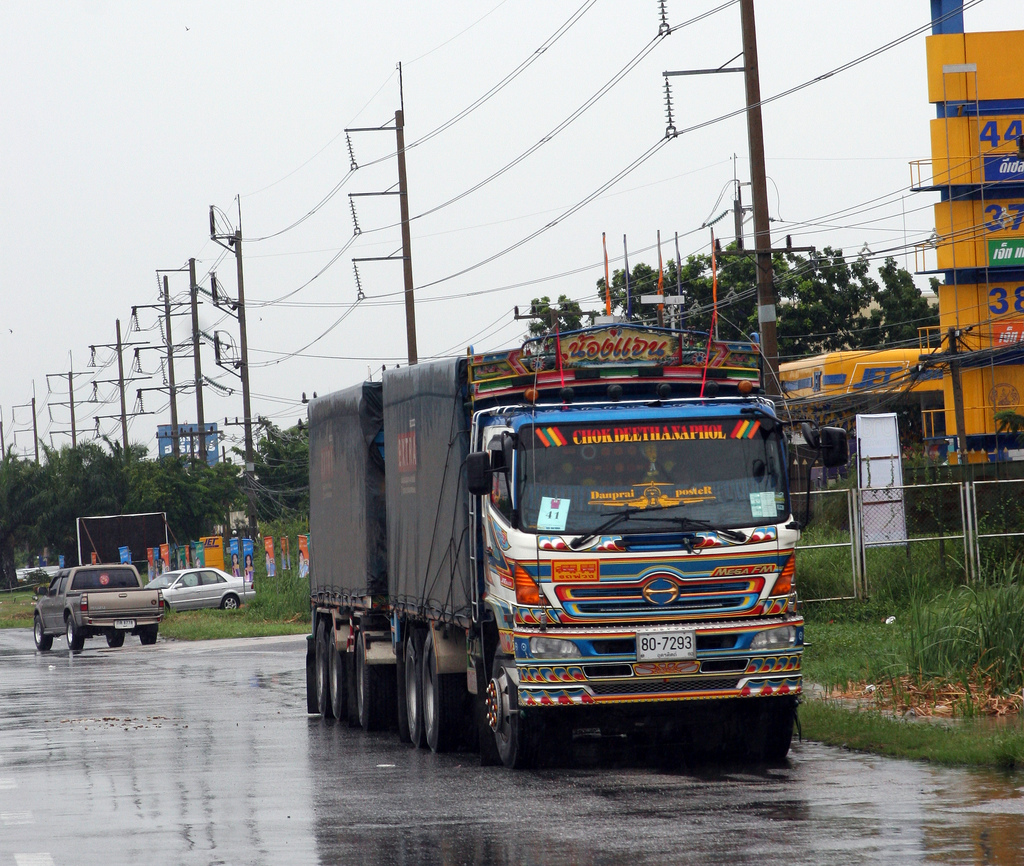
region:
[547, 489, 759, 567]
windshield wiper on the truck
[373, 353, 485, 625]
black tarp on the truck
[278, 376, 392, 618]
black tarp on the truck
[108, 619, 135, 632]
license plate on the pickup truck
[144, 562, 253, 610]
Car in front of the pickup truck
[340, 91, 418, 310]
Electric wires on the pole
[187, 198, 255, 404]
Electric wires on the pole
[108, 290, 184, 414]
Electric wires on the pole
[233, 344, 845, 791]
semi with two trailers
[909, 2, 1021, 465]
orange and blue gas price sign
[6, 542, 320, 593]
line of orange and blue flags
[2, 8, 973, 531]
powerlines on the side of the road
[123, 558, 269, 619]
silver car parked in grass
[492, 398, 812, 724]
blue and orange painting on front of truck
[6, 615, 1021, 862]
asphalt wet from the rain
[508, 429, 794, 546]
windshield on the truck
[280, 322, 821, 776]
truck in the street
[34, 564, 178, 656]
pickup truck on the street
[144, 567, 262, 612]
car parked on grass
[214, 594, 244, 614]
black tire on car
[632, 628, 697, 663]
license plate on truck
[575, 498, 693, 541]
windshield wiper on truck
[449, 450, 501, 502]
side view mirror on truck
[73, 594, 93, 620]
brake light on truck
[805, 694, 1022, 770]
green grass on the ground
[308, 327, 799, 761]
A trailer truck by the roadside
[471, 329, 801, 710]
The colorful front side of the truck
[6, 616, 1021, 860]
The cemented surface of the road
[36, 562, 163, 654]
A van on the road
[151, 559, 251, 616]
A white parked car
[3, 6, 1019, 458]
A row of electricity poles and overhead cables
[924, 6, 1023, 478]
A yellow colored building by the roadside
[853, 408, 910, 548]
An electricity junction box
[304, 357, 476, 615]
The two containers loaded on the truck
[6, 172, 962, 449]
The hazy sky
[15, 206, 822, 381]
The wooden poles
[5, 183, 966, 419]
A set of wooden poles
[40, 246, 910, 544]
A forest of trees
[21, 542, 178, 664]
The tan truck on the road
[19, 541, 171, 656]
A tan truck on the road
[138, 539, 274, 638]
The parked silver vehicle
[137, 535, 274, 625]
A parked silver vehicle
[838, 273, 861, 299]
green leaves on the tree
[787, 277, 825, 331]
green leaves on the tree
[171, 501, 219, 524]
green leaves on the tree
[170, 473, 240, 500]
green leaves on the tree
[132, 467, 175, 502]
green leaves on the tree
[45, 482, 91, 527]
green leaves on the tree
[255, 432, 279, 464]
green leaves on the tree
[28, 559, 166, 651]
tan truck with four tires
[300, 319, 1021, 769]
truck next to a metal fence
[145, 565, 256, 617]
parked silver car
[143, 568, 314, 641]
silver car parked in the grass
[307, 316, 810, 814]
this is a truck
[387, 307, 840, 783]
the truck is a semi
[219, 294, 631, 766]
the trucks is long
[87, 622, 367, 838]
the street is wet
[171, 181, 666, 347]
these are power lines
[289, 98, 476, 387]
the pole is wooden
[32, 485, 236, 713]
the truck is golden